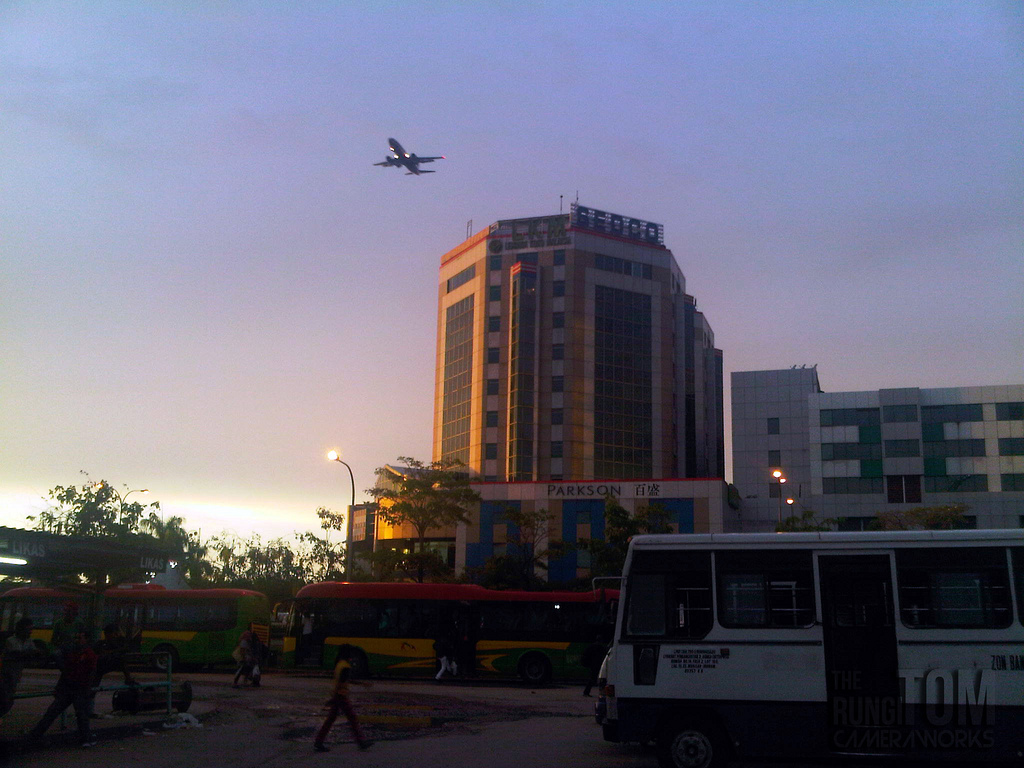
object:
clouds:
[3, 225, 1020, 478]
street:
[2, 665, 665, 763]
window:
[629, 575, 664, 633]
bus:
[290, 582, 622, 686]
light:
[327, 451, 338, 460]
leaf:
[140, 489, 149, 492]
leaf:
[151, 502, 157, 508]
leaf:
[134, 526, 138, 531]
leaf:
[82, 486, 86, 491]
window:
[820, 410, 832, 427]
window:
[833, 409, 845, 426]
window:
[844, 407, 857, 424]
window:
[857, 408, 870, 424]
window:
[869, 407, 881, 424]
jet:
[373, 138, 446, 176]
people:
[316, 643, 352, 762]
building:
[732, 368, 1024, 532]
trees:
[74, 479, 113, 535]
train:
[608, 507, 1003, 717]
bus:
[13, 585, 271, 668]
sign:
[571, 204, 664, 246]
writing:
[548, 485, 620, 496]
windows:
[970, 403, 983, 422]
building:
[433, 202, 724, 480]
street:
[0, 678, 621, 763]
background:
[0, 0, 1023, 405]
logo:
[0, 537, 166, 573]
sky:
[0, 4, 1020, 389]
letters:
[511, 220, 522, 241]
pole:
[338, 461, 355, 581]